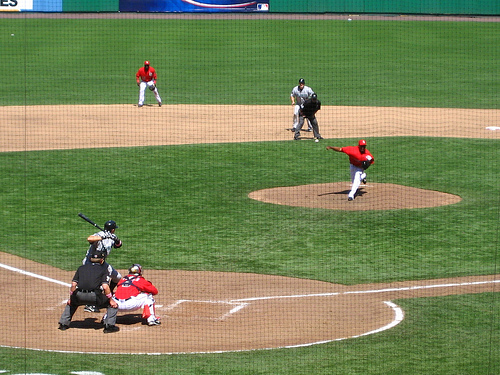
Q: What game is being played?
A: Baseball.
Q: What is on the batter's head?
A: A helmet.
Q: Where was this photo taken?
A: Baseball game.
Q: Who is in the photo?
A: Baseball players.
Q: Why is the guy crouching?
A: He's the catcher.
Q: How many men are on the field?
A: 7.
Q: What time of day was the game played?
A: Afternoon.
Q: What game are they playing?
A: Baseball.